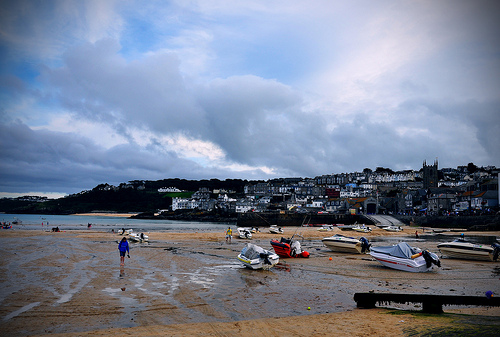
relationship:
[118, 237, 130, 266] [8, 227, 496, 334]
woman on sand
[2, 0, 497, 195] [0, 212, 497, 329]
clouds above land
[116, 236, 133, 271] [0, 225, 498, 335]
person on beach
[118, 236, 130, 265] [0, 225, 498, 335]
woman on beach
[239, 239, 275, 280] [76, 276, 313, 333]
boats on sand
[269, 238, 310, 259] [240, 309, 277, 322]
boat on sand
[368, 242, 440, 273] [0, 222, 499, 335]
boat on beach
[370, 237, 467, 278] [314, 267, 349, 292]
boat on sand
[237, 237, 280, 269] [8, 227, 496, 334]
boat in sand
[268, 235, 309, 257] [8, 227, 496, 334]
boat in sand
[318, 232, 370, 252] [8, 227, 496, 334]
boat in sand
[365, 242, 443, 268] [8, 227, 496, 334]
boat in sand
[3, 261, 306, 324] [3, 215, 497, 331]
water on beach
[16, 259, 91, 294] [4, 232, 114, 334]
low tide on a beach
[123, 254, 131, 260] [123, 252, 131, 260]
shoe in hand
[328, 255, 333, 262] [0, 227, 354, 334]
roundobject in sand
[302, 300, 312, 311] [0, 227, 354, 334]
roundobject in sand